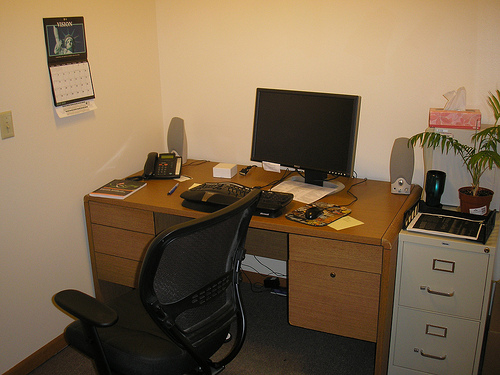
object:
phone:
[143, 150, 182, 181]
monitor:
[248, 87, 360, 179]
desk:
[83, 159, 424, 375]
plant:
[404, 88, 499, 200]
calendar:
[41, 17, 101, 120]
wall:
[1, 1, 164, 372]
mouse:
[306, 206, 324, 219]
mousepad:
[285, 202, 353, 228]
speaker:
[167, 115, 185, 163]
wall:
[158, 0, 500, 212]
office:
[0, 0, 498, 374]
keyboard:
[179, 183, 294, 218]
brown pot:
[456, 185, 493, 220]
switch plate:
[0, 110, 16, 141]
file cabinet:
[398, 241, 490, 321]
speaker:
[386, 137, 415, 196]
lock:
[326, 270, 337, 278]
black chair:
[53, 186, 264, 374]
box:
[428, 107, 480, 129]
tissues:
[442, 83, 470, 111]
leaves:
[420, 133, 429, 148]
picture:
[46, 24, 88, 58]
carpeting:
[29, 280, 369, 374]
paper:
[326, 214, 362, 231]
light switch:
[1, 111, 15, 140]